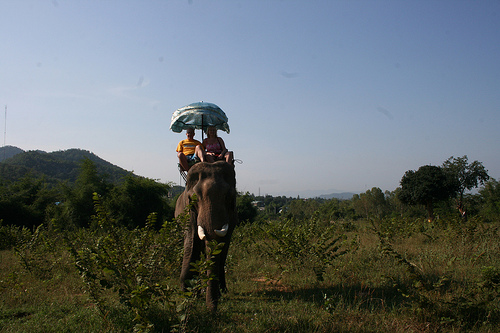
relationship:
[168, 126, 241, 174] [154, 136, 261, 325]
people riding elephant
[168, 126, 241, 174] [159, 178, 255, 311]
people riding elephant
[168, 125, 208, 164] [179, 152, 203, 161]
man wearing shirt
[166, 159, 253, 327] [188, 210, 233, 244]
elephant with tusks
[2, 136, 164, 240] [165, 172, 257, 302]
hills behind elephant